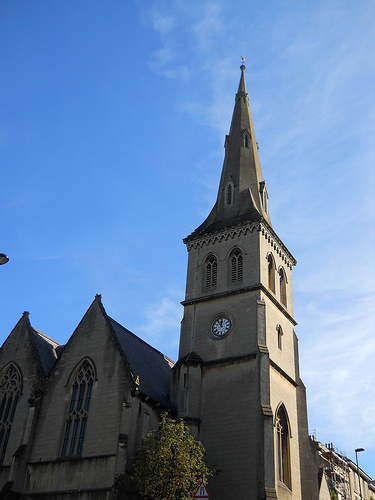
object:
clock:
[210, 315, 233, 339]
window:
[0, 358, 25, 469]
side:
[0, 290, 178, 498]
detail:
[124, 385, 172, 443]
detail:
[94, 291, 104, 303]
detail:
[8, 392, 46, 494]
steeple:
[170, 54, 307, 497]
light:
[353, 445, 367, 498]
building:
[1, 54, 373, 498]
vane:
[239, 53, 249, 72]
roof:
[95, 290, 178, 416]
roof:
[24, 309, 67, 382]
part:
[53, 41, 125, 88]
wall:
[174, 221, 266, 497]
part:
[148, 437, 189, 470]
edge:
[113, 385, 126, 491]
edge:
[253, 295, 277, 500]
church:
[0, 52, 373, 499]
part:
[166, 464, 187, 487]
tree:
[106, 410, 221, 500]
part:
[59, 407, 85, 460]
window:
[57, 353, 101, 459]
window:
[273, 398, 295, 494]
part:
[277, 417, 283, 484]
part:
[354, 445, 366, 454]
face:
[212, 316, 231, 337]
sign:
[190, 479, 213, 498]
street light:
[0, 249, 10, 267]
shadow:
[105, 311, 174, 413]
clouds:
[148, 295, 174, 335]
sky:
[0, 4, 375, 481]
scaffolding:
[319, 438, 351, 499]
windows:
[198, 248, 223, 294]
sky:
[37, 10, 176, 281]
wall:
[198, 354, 264, 497]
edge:
[129, 381, 178, 419]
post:
[355, 452, 365, 498]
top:
[182, 51, 301, 267]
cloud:
[312, 243, 367, 434]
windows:
[222, 243, 250, 288]